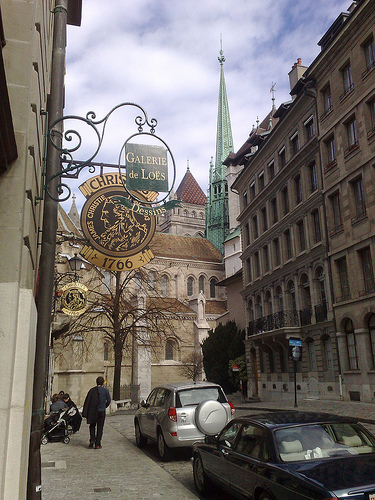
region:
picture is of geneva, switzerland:
[1, 0, 373, 498]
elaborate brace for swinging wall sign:
[41, 93, 183, 222]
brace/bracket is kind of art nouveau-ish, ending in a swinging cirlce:
[40, 98, 183, 230]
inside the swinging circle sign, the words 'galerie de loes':
[108, 130, 181, 218]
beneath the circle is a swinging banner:
[104, 191, 186, 219]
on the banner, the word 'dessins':
[126, 198, 168, 218]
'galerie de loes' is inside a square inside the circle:
[124, 143, 169, 190]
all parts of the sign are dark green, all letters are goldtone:
[42, 87, 182, 220]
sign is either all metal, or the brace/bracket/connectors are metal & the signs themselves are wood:
[42, 94, 186, 219]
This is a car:
[125, 360, 238, 467]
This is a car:
[197, 393, 366, 487]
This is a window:
[270, 280, 288, 320]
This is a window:
[296, 268, 311, 321]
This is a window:
[332, 307, 360, 379]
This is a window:
[327, 247, 351, 305]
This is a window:
[322, 185, 348, 241]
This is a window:
[304, 201, 324, 250]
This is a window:
[297, 218, 312, 261]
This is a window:
[290, 164, 309, 209]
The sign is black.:
[121, 141, 171, 187]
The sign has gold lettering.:
[124, 143, 173, 188]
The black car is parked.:
[183, 409, 369, 497]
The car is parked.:
[132, 382, 230, 447]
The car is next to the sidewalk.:
[128, 382, 234, 460]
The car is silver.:
[129, 382, 223, 453]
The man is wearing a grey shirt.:
[73, 364, 119, 447]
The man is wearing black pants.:
[80, 409, 106, 452]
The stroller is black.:
[42, 402, 81, 447]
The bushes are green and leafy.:
[197, 319, 244, 390]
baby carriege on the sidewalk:
[38, 403, 79, 444]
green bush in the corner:
[199, 321, 244, 399]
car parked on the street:
[130, 380, 236, 460]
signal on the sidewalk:
[287, 337, 303, 410]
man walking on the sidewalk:
[80, 375, 119, 451]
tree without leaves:
[49, 260, 197, 406]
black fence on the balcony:
[243, 307, 303, 340]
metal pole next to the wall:
[22, 1, 70, 499]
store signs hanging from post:
[45, 115, 179, 274]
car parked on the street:
[190, 408, 374, 498]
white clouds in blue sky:
[90, 9, 135, 60]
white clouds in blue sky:
[79, 63, 104, 86]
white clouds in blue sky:
[125, 8, 161, 35]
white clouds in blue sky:
[132, 63, 153, 95]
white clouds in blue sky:
[168, 41, 198, 90]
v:
[171, 73, 205, 128]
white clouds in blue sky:
[217, 1, 272, 41]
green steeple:
[208, 66, 246, 127]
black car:
[227, 406, 348, 486]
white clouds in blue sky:
[171, 96, 200, 141]